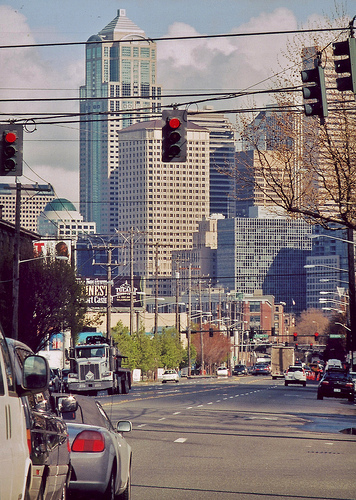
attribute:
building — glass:
[64, 3, 166, 243]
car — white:
[154, 364, 181, 386]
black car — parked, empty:
[315, 368, 354, 400]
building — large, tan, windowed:
[78, 8, 161, 232]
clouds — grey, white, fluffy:
[0, 5, 354, 193]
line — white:
[132, 382, 220, 394]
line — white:
[154, 390, 262, 407]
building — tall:
[110, 92, 218, 282]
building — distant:
[78, 9, 160, 272]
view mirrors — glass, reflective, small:
[20, 350, 51, 390]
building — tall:
[37, 199, 96, 238]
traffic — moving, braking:
[217, 356, 353, 401]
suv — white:
[281, 362, 308, 390]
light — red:
[155, 94, 218, 173]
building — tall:
[39, 195, 100, 237]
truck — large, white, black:
[64, 331, 132, 394]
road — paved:
[1, 374, 352, 497]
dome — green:
[41, 198, 75, 209]